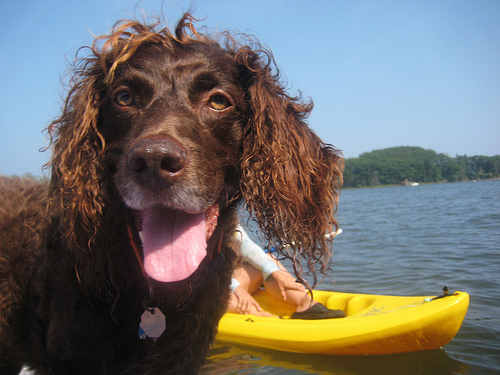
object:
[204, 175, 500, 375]
water body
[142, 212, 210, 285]
pink tounge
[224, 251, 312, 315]
woman/legs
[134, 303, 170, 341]
symbol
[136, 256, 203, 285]
tip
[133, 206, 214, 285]
tongue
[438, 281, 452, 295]
handle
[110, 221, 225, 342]
collar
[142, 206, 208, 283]
tongue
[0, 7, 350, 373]
dog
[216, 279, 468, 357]
kayak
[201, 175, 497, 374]
water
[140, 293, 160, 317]
loop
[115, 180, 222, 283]
mouth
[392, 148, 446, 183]
large trees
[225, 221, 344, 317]
person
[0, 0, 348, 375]
dog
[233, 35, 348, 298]
ear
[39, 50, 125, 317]
ear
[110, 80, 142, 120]
eye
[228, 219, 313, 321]
woman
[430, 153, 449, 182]
trees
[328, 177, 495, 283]
water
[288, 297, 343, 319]
shoes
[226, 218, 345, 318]
man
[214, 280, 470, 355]
raft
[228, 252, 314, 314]
legs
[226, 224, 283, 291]
shirt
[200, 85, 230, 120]
eye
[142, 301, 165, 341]
tag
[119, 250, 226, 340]
chain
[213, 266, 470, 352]
boat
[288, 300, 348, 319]
wear